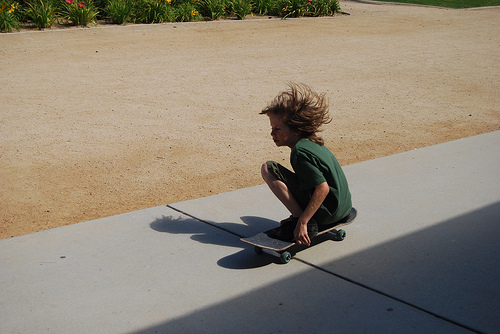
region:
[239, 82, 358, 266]
young boy riding skateboard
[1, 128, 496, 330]
sidewalk is light gray concrete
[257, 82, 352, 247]
boy wearing a a dark green shirt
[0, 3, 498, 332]
light brown dirt next to sidewalk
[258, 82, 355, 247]
boy has long brown hair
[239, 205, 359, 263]
black skateboard with bluish/green wheels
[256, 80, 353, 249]
kid on a skateboard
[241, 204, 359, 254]
black skateboard deck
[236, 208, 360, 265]
skateboard on a sidewalk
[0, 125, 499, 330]
grey cement sidewalk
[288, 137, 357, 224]
green colored tee shirt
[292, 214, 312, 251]
left hand on the board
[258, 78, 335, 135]
brown hair flying in the air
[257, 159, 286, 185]
bent left knee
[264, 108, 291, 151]
left side of the kid's face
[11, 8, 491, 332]
Photo taken during the day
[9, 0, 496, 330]
The weather is sunny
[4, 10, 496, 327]
Photo taken in summer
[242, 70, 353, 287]
Boy riding a skateboard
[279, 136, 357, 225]
Green shirt on the bou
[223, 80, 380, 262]
Boy with long hair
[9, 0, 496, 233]
The dirt is brown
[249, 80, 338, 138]
The boy's hair is in the air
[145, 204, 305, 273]
The boy's shadow on the sidewalk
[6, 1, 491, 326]
One person in the photo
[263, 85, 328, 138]
boy with blond hair flying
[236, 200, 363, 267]
black skateboard on pavement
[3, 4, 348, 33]
greenery and flowers in background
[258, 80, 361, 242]
boy crouching on skateboard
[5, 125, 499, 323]
grey concrete slab with boy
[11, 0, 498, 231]
sandy dirt like surround to sidewalk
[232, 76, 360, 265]
boy sitting on black skateboard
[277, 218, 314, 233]
boy wearing black shoes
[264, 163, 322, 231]
boy wearing green shorts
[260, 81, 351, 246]
young boy on a skateboard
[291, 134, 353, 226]
green shirt on the boy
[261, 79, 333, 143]
hair blowing in the wind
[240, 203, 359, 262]
skateboard under the boy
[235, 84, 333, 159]
head of a kid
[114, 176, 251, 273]
shadow on the ground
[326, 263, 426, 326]
line on the ground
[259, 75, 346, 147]
long hair on kid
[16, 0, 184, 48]
plants in the distance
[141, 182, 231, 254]
shadow and line on ground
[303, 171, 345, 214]
elbow of the kid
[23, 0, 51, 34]
small plant by the kid skating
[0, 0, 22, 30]
small plant by the kid skating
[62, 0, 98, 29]
small plant by the kid skating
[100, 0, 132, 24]
small plant by the kid skating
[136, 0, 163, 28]
small plant by the kid skating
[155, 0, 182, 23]
small plant by the kid skating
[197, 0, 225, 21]
small plant by the kid skating